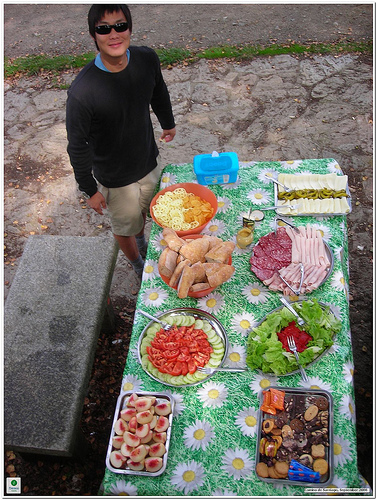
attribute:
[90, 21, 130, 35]
sunglasses — in the picture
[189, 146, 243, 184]
case — in the picture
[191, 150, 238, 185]
box — in the picture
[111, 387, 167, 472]
peaches — in the picture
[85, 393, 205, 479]
cookies — in the picture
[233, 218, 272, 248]
mustard — in the picture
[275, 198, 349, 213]
cheeses — in the picture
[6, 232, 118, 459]
stone bench — in the picture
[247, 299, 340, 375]
lettuce — in the picture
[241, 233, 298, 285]
salami — in the picture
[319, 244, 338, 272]
tray — in the picture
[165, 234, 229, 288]
bread — in the picture